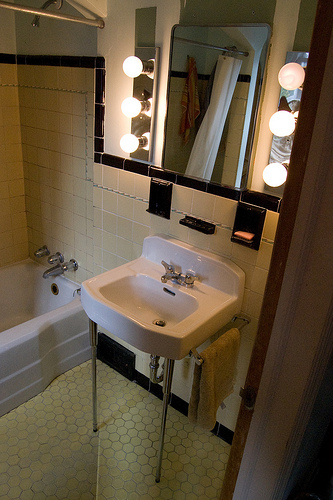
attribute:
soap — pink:
[236, 228, 254, 241]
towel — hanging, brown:
[208, 335, 235, 405]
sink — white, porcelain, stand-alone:
[134, 234, 222, 335]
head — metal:
[27, 14, 43, 31]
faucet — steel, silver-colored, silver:
[45, 264, 63, 277]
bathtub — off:
[6, 267, 83, 375]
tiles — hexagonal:
[123, 439, 134, 455]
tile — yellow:
[113, 447, 128, 460]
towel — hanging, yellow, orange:
[183, 56, 200, 122]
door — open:
[282, 208, 332, 412]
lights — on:
[123, 56, 143, 77]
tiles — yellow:
[106, 190, 118, 215]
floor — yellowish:
[43, 433, 85, 475]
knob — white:
[123, 135, 139, 155]